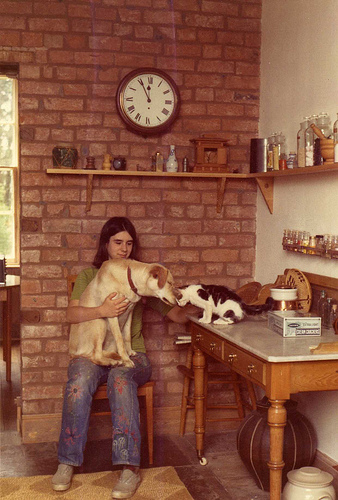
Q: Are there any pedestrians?
A: No, there are no pedestrians.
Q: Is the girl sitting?
A: Yes, the girl is sitting.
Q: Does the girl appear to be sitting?
A: Yes, the girl is sitting.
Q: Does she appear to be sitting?
A: Yes, the girl is sitting.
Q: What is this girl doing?
A: The girl is sitting.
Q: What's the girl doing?
A: The girl is sitting.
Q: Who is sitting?
A: The girl is sitting.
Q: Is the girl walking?
A: No, the girl is sitting.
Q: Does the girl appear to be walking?
A: No, the girl is sitting.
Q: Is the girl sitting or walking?
A: The girl is sitting.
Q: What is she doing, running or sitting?
A: The girl is sitting.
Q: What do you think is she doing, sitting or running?
A: The girl is sitting.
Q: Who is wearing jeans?
A: The girl is wearing jeans.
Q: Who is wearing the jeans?
A: The girl is wearing jeans.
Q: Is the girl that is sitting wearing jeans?
A: Yes, the girl is wearing jeans.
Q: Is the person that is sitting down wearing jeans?
A: Yes, the girl is wearing jeans.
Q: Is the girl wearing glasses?
A: No, the girl is wearing jeans.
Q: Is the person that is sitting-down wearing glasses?
A: No, the girl is wearing jeans.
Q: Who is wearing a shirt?
A: The girl is wearing a shirt.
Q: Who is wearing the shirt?
A: The girl is wearing a shirt.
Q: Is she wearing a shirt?
A: Yes, the girl is wearing a shirt.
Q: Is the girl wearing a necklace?
A: No, the girl is wearing a shirt.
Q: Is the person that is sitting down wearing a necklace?
A: No, the girl is wearing a shirt.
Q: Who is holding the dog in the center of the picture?
A: The girl is holding the dog.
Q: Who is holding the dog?
A: The girl is holding the dog.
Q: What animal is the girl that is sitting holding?
A: The girl is holding the dog.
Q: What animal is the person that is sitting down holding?
A: The girl is holding the dog.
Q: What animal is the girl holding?
A: The girl is holding the dog.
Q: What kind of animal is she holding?
A: The girl is holding the dog.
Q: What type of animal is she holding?
A: The girl is holding the dog.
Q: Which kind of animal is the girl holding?
A: The girl is holding the dog.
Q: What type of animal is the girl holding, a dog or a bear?
A: The girl is holding a dog.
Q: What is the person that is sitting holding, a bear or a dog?
A: The girl is holding a dog.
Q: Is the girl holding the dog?
A: Yes, the girl is holding the dog.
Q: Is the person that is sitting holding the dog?
A: Yes, the girl is holding the dog.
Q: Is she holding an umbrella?
A: No, the girl is holding the dog.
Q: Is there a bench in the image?
A: No, there are no benches.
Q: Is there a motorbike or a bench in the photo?
A: No, there are no benches or motorcycles.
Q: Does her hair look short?
A: Yes, the hair is short.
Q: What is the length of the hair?
A: The hair is short.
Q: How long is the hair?
A: The hair is short.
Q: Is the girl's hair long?
A: No, the hair is short.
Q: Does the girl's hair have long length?
A: No, the hair is short.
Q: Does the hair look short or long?
A: The hair is short.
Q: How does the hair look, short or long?
A: The hair is short.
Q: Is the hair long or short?
A: The hair is short.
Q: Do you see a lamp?
A: No, there are no lamps.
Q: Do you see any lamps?
A: No, there are no lamps.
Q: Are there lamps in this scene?
A: No, there are no lamps.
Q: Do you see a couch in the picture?
A: No, there are no couches.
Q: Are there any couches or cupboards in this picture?
A: No, there are no couches or cupboards.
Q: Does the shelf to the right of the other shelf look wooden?
A: Yes, the shelf is wooden.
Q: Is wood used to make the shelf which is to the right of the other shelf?
A: Yes, the shelf is made of wood.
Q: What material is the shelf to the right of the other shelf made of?
A: The shelf is made of wood.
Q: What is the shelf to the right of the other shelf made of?
A: The shelf is made of wood.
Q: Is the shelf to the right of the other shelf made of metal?
A: No, the shelf is made of wood.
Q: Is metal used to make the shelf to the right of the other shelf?
A: No, the shelf is made of wood.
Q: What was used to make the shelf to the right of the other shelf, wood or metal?
A: The shelf is made of wood.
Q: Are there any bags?
A: No, there are no bags.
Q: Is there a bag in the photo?
A: No, there are no bags.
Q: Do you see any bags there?
A: No, there are no bags.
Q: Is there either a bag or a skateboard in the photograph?
A: No, there are no bags or skateboards.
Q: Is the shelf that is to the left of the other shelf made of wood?
A: Yes, the shelf is made of wood.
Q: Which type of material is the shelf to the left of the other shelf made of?
A: The shelf is made of wood.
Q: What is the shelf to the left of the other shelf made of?
A: The shelf is made of wood.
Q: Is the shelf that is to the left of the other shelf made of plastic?
A: No, the shelf is made of wood.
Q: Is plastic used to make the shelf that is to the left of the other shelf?
A: No, the shelf is made of wood.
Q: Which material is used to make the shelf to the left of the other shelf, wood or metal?
A: The shelf is made of wood.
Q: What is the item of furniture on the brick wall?
A: The piece of furniture is a shelf.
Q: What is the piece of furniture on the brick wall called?
A: The piece of furniture is a shelf.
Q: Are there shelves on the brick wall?
A: Yes, there is a shelf on the wall.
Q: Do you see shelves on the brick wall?
A: Yes, there is a shelf on the wall.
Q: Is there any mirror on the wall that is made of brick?
A: No, there is a shelf on the wall.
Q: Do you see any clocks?
A: Yes, there is a clock.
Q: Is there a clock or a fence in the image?
A: Yes, there is a clock.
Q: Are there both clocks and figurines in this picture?
A: No, there is a clock but no figurines.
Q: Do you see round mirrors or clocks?
A: Yes, there is a round clock.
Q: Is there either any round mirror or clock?
A: Yes, there is a round clock.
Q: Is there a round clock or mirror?
A: Yes, there is a round clock.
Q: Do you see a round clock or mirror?
A: Yes, there is a round clock.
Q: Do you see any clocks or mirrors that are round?
A: Yes, the clock is round.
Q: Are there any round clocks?
A: Yes, there is a round clock.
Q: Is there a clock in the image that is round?
A: Yes, there is a clock that is round.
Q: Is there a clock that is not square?
A: Yes, there is a round clock.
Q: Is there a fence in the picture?
A: No, there are no fences.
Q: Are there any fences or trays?
A: No, there are no fences or trays.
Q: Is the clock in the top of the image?
A: Yes, the clock is in the top of the image.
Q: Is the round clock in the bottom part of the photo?
A: No, the clock is in the top of the image.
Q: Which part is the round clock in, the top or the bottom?
A: The clock is in the top of the image.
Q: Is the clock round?
A: Yes, the clock is round.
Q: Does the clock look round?
A: Yes, the clock is round.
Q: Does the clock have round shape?
A: Yes, the clock is round.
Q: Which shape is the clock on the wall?
A: The clock is round.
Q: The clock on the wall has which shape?
A: The clock is round.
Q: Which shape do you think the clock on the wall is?
A: The clock is round.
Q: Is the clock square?
A: No, the clock is round.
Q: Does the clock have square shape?
A: No, the clock is round.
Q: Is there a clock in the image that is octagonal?
A: No, there is a clock but it is round.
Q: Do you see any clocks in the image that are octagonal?
A: No, there is a clock but it is round.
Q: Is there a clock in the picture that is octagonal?
A: No, there is a clock but it is round.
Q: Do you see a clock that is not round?
A: No, there is a clock but it is round.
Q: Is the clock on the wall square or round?
A: The clock is round.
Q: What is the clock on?
A: The clock is on the wall.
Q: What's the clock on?
A: The clock is on the wall.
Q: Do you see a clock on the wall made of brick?
A: Yes, there is a clock on the wall.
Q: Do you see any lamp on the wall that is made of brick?
A: No, there is a clock on the wall.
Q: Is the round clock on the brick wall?
A: Yes, the clock is on the wall.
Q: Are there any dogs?
A: Yes, there is a dog.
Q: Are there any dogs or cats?
A: Yes, there is a dog.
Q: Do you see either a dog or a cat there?
A: Yes, there is a dog.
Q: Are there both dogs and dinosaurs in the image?
A: No, there is a dog but no dinosaurs.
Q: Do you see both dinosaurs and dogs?
A: No, there is a dog but no dinosaurs.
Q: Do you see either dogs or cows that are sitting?
A: Yes, the dog is sitting.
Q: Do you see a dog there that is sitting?
A: Yes, there is a dog that is sitting.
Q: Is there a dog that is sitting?
A: Yes, there is a dog that is sitting.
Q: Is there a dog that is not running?
A: Yes, there is a dog that is sitting.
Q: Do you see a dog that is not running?
A: Yes, there is a dog that is sitting .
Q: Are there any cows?
A: No, there are no cows.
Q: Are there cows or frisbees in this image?
A: No, there are no cows or frisbees.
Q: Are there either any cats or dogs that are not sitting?
A: No, there is a dog but it is sitting.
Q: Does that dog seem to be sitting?
A: Yes, the dog is sitting.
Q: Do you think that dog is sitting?
A: Yes, the dog is sitting.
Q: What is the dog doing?
A: The dog is sitting.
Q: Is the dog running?
A: No, the dog is sitting.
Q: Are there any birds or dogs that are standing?
A: No, there is a dog but it is sitting.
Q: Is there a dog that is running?
A: No, there is a dog but it is sitting.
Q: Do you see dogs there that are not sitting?
A: No, there is a dog but it is sitting.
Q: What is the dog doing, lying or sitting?
A: The dog is sitting.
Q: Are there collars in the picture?
A: Yes, there is a collar.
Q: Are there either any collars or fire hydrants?
A: Yes, there is a collar.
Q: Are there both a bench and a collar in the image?
A: No, there is a collar but no benches.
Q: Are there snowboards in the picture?
A: No, there are no snowboards.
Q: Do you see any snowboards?
A: No, there are no snowboards.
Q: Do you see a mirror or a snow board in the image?
A: No, there are no snowboards or mirrors.